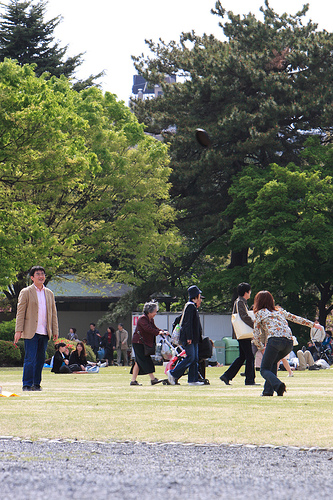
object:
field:
[0, 363, 333, 448]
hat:
[187, 285, 202, 302]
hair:
[30, 265, 46, 282]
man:
[14, 266, 59, 392]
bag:
[231, 300, 266, 340]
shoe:
[166, 370, 176, 386]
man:
[166, 284, 205, 386]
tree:
[0, 55, 197, 322]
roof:
[47, 269, 136, 296]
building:
[46, 263, 179, 345]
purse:
[199, 337, 213, 361]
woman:
[166, 285, 205, 385]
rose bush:
[0, 339, 23, 368]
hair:
[142, 299, 159, 315]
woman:
[130, 302, 170, 386]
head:
[30, 265, 45, 286]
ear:
[30, 276, 34, 281]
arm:
[15, 292, 26, 334]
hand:
[14, 332, 21, 344]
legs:
[22, 338, 47, 389]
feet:
[23, 385, 43, 391]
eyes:
[38, 273, 44, 276]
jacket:
[15, 283, 58, 341]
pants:
[23, 333, 49, 389]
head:
[142, 300, 158, 318]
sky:
[0, 0, 333, 108]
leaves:
[0, 77, 178, 288]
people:
[14, 265, 333, 397]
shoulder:
[186, 302, 195, 313]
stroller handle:
[160, 329, 185, 355]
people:
[51, 341, 93, 374]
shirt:
[253, 305, 316, 351]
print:
[259, 312, 293, 338]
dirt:
[0, 436, 333, 500]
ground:
[0, 362, 333, 499]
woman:
[252, 290, 322, 397]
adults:
[130, 285, 204, 386]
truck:
[131, 311, 232, 360]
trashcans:
[213, 336, 240, 366]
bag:
[170, 302, 194, 345]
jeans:
[260, 335, 293, 396]